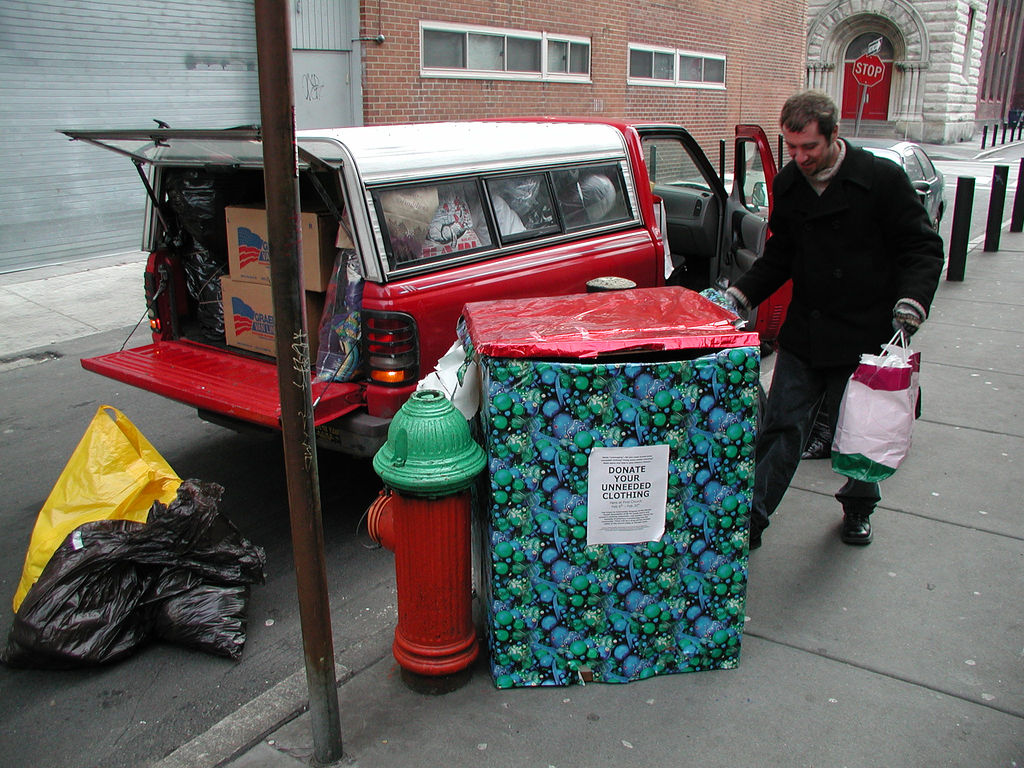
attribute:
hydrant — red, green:
[363, 391, 491, 696]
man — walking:
[724, 91, 946, 553]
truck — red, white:
[57, 118, 781, 458]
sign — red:
[851, 55, 889, 135]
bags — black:
[13, 481, 268, 670]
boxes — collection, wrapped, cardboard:
[220, 204, 341, 366]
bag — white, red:
[828, 329, 924, 480]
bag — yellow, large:
[11, 404, 184, 615]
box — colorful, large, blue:
[459, 283, 760, 690]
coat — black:
[726, 141, 947, 366]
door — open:
[720, 123, 779, 284]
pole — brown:
[252, 0, 344, 764]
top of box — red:
[464, 286, 761, 356]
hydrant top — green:
[370, 388, 491, 496]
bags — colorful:
[13, 403, 271, 668]